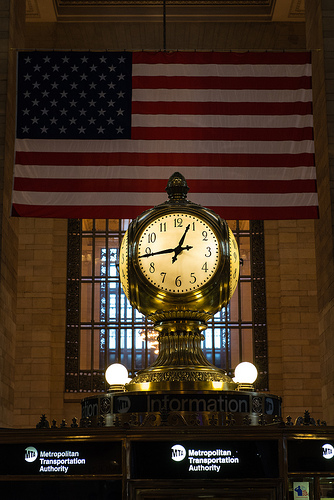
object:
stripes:
[10, 166, 317, 182]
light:
[102, 364, 131, 386]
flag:
[8, 49, 321, 221]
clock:
[119, 172, 251, 393]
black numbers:
[147, 230, 156, 238]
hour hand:
[170, 225, 190, 262]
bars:
[65, 216, 263, 376]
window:
[98, 245, 233, 376]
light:
[231, 359, 259, 391]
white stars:
[116, 127, 126, 136]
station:
[6, 4, 332, 496]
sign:
[162, 439, 249, 480]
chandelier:
[28, 404, 86, 429]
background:
[0, 0, 333, 500]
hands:
[136, 242, 195, 260]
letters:
[142, 393, 283, 416]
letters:
[17, 448, 88, 475]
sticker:
[316, 437, 332, 466]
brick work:
[31, 297, 52, 312]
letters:
[35, 462, 68, 474]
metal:
[12, 407, 330, 432]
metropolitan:
[187, 444, 234, 461]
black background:
[127, 442, 277, 478]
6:
[174, 274, 183, 286]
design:
[34, 414, 52, 427]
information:
[143, 382, 256, 415]